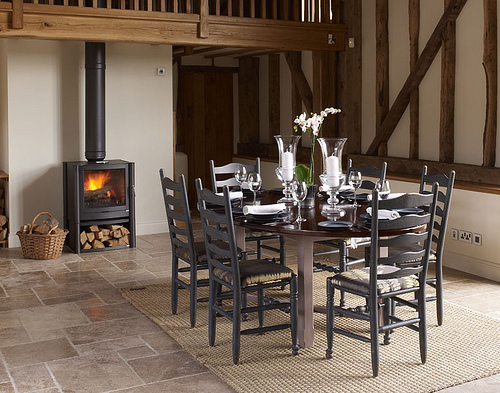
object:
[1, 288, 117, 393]
floor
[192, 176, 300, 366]
chair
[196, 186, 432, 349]
table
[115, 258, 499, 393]
rug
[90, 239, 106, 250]
wood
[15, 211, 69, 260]
basket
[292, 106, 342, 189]
flower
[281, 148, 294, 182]
candle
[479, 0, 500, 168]
wall panels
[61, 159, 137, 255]
stove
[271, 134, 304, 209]
holder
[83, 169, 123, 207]
fire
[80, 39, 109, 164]
stove pipe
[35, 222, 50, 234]
logs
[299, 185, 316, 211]
vase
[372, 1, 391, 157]
wood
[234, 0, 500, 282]
wall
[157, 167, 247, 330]
chair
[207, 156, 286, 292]
chair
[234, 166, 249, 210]
glass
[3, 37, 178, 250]
wall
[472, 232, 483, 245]
socket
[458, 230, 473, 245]
socket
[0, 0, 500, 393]
room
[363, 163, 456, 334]
chair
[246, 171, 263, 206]
glass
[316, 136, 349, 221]
candleholder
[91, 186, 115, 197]
wood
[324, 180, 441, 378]
chair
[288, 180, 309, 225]
glass